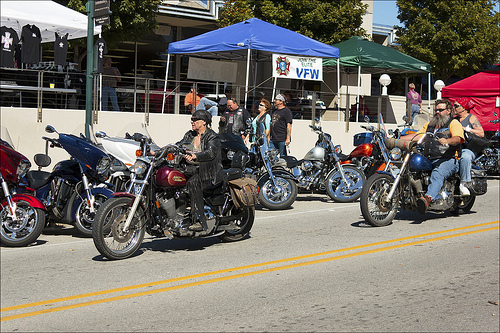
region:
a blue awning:
[163, 13, 344, 120]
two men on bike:
[416, 93, 486, 210]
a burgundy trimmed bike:
[94, 140, 260, 255]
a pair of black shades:
[186, 115, 198, 122]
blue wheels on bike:
[260, 168, 362, 208]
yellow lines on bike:
[0, 221, 498, 323]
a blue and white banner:
[267, 55, 327, 82]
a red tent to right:
[438, 67, 499, 129]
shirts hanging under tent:
[1, 20, 68, 60]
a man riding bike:
[95, 107, 261, 259]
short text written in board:
[265, 42, 372, 97]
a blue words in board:
[281, 52, 333, 81]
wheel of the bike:
[83, 200, 182, 270]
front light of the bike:
[123, 155, 159, 180]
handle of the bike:
[123, 121, 216, 173]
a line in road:
[73, 213, 498, 308]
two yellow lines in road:
[5, 219, 498, 324]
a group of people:
[130, 86, 497, 233]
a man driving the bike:
[81, 97, 301, 305]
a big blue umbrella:
[167, 14, 343, 104]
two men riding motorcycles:
[140, 102, 457, 224]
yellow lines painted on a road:
[31, 219, 491, 332]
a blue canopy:
[163, 31, 334, 131]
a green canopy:
[332, 47, 431, 81]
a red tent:
[451, 57, 497, 134]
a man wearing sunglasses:
[186, 101, 211, 136]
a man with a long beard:
[416, 94, 449, 135]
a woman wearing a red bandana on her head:
[450, 99, 476, 118]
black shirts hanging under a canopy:
[1, 25, 84, 60]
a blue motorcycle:
[58, 136, 116, 194]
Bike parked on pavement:
[106, 127, 270, 249]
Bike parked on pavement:
[365, 117, 499, 244]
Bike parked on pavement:
[288, 120, 355, 209]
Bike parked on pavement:
[237, 120, 304, 222]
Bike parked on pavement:
[24, 127, 133, 268]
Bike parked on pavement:
[5, 99, 47, 246]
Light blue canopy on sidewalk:
[160, 4, 325, 75]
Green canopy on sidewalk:
[334, 21, 447, 110]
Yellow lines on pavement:
[30, 285, 82, 331]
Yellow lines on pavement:
[76, 252, 149, 318]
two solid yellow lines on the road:
[1, 219, 498, 330]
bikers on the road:
[88, 95, 489, 260]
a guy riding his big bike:
[85, 108, 266, 265]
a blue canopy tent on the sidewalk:
[158, 15, 343, 118]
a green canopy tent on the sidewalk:
[321, 33, 434, 120]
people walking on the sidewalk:
[216, 93, 296, 165]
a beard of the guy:
[427, 113, 452, 130]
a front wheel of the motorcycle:
[89, 190, 147, 260]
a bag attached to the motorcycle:
[225, 177, 262, 212]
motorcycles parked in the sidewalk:
[258, 127, 369, 209]